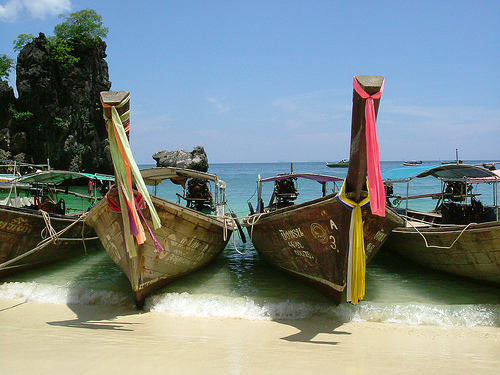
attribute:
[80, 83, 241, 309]
boat — empty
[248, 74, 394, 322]
boat — wooden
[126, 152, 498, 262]
waves — small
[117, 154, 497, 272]
sea — blue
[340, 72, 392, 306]
front — streamlined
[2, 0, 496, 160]
sky — clear, blue, bright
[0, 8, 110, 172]
trees — green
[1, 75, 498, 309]
boats — wood, brown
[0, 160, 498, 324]
water — blue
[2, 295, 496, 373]
sand — tan